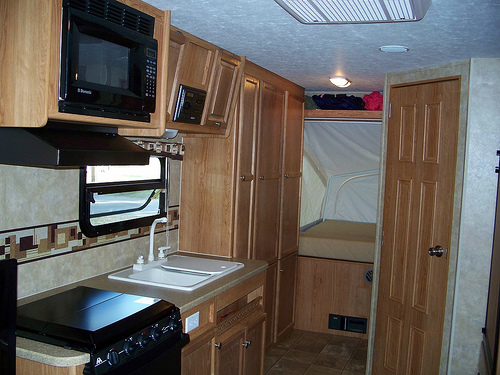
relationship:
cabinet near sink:
[234, 74, 254, 256] [122, 253, 239, 288]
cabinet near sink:
[262, 85, 281, 258] [122, 253, 239, 288]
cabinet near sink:
[278, 94, 302, 254] [122, 253, 239, 288]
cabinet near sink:
[277, 260, 296, 335] [122, 253, 239, 288]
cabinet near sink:
[265, 265, 275, 347] [122, 253, 239, 288]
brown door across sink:
[372, 80, 458, 373] [109, 251, 249, 292]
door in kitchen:
[365, 87, 497, 352] [2, 0, 495, 373]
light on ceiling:
[323, 62, 353, 91] [160, 2, 490, 84]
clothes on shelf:
[322, 92, 381, 107] [300, 102, 382, 119]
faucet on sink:
[134, 216, 174, 268] [109, 251, 249, 292]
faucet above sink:
[134, 216, 174, 268] [109, 248, 245, 290]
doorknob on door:
[424, 236, 443, 258] [354, 71, 466, 373]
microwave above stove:
[62, 16, 159, 114] [22, 269, 187, 373]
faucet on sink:
[134, 216, 174, 268] [111, 246, 245, 288]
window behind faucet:
[84, 156, 166, 232] [131, 212, 172, 268]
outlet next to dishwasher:
[183, 309, 200, 332] [16, 283, 184, 373]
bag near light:
[343, 77, 394, 130] [316, 57, 381, 95]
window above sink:
[84, 156, 166, 232] [84, 212, 283, 367]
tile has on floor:
[286, 324, 363, 366] [270, 327, 373, 366]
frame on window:
[77, 150, 168, 238] [88, 156, 161, 221]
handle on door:
[424, 242, 450, 259] [331, 75, 480, 374]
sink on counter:
[122, 248, 229, 298] [84, 245, 272, 302]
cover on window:
[83, 166, 174, 226] [84, 156, 166, 232]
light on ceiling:
[323, 62, 353, 91] [245, 23, 342, 66]